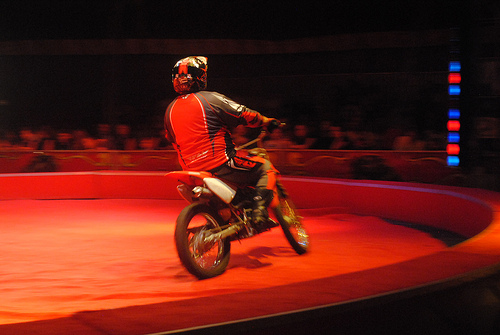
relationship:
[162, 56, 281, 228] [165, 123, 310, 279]
biker riding bike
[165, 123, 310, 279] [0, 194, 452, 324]
bike on dirt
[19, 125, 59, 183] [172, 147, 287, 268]
man riding motorcycle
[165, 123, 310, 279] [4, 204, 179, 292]
bike on dirt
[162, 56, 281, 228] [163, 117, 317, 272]
biker riding on motorcycle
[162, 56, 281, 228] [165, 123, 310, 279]
biker riding on bike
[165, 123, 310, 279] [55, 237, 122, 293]
bike on dirt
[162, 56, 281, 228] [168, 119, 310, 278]
biker riding motorcyle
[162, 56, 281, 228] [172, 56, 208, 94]
biker wearing helmet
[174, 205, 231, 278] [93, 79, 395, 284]
motorcycle wheel on motorcycle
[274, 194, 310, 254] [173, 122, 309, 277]
tire on motorcycle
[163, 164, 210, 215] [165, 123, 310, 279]
muffler motorcyle on bike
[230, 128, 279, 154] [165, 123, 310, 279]
handle bar on bike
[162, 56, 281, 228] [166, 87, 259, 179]
biker wearing jacket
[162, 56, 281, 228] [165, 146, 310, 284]
biker riding bike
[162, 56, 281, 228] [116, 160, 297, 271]
biker riding motorbike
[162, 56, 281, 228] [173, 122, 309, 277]
biker riding motorcycle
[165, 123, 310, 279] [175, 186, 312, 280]
bike has wheels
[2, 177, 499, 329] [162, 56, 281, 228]
track surrounding biker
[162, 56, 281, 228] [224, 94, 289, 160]
biker holding handlebar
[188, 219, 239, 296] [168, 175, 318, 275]
spokes on motorcycle wheel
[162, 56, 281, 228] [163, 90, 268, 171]
biker wearing jacket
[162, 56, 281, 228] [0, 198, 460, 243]
biker beside track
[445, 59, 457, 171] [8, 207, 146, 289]
light shining on track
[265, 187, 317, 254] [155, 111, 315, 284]
tire of motorcycle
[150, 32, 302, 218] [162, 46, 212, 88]
biker wearing helmet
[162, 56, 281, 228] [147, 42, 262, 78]
biker wearing helmet